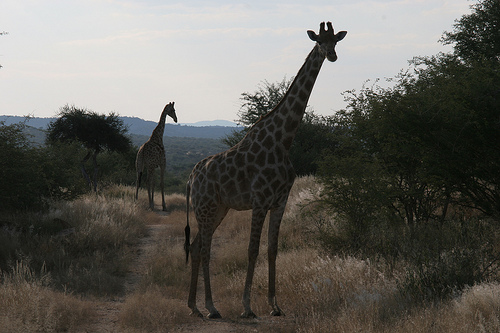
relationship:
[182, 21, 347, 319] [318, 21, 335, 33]
brown giraffe has horns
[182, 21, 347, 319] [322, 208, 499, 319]
brown giraffe in foreground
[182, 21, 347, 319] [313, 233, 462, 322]
brown giraffe in foreground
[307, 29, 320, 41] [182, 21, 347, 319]
ear on brown giraffe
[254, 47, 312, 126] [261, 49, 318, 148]
mane on neck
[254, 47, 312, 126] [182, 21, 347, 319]
mane on brown giraffe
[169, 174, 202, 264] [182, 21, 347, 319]
tail on brown giraffe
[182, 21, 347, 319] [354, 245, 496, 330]
brown giraffe in foreground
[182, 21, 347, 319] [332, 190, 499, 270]
brown giraffe in foreground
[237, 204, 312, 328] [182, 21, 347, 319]
legs on brown giraffe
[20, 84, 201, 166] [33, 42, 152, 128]
mountains in distant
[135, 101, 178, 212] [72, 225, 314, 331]
brown giraffe in ground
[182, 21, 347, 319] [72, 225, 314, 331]
brown giraffe in ground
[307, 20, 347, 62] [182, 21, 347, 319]
head of a brown giraffe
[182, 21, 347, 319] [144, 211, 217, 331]
brown giraffe in road